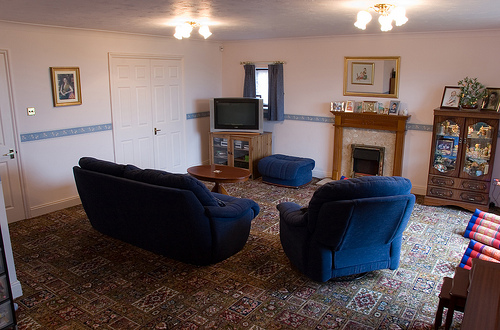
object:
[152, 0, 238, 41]
lights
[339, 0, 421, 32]
lights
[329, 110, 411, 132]
mantel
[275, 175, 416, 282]
chair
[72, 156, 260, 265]
couch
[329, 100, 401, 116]
pictures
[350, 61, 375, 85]
picture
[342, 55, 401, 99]
mirror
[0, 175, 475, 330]
carpet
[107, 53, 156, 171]
doors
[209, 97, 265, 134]
television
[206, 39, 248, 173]
corner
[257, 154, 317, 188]
footstool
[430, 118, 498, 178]
door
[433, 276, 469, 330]
side tables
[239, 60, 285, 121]
curtains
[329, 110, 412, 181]
fireplace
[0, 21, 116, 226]
wall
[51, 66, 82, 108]
picture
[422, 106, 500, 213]
curio cabinet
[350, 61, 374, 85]
reflection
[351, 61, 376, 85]
print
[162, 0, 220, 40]
fixture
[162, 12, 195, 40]
lamp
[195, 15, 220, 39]
lamp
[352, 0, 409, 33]
fixture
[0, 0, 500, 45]
celing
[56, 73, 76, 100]
photograph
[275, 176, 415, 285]
recliner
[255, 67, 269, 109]
window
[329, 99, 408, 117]
items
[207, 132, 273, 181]
tv cabinet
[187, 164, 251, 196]
coffee table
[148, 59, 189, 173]
door